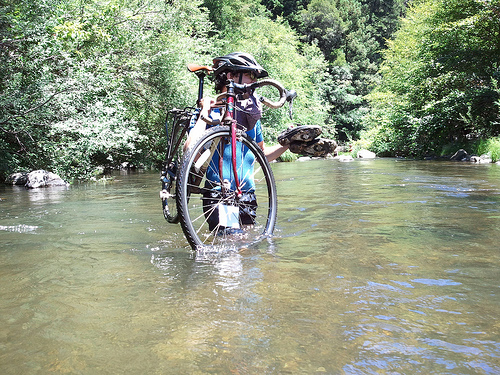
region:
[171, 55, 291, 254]
a person carrying a bike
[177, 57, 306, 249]
a person wading through water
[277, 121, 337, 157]
a person carrying a pair of shoes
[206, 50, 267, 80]
a black bike helmet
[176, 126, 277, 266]
the front wheel of a bike in the water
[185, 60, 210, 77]
an orange bike seat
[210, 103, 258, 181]
a person wearing a blue shirt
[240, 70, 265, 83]
a person wearing glasses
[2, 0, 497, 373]
a stream surrounded by trees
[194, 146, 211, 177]
a reflector in bike spokes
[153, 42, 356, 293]
the bike is in the water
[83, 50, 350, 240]
the man is in the water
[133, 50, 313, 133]
the man is wearing a helmet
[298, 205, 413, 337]
the water is calm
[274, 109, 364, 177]
the man is holding his shoes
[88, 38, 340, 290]
the man is walking in water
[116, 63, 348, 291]
the water is past the mans knees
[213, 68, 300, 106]
the man has on sunglasses.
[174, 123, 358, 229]
the bike has red on it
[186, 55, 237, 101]
the seat is red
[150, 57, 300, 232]
man is carrying bike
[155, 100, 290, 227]
black wheel on bike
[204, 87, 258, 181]
red frame on bike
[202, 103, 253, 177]
man has blue shirt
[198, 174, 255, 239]
man has black pants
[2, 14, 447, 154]
green trees behind man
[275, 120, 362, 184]
man is carrying shoes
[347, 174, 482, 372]
water is dark grey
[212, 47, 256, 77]
man has grey helmet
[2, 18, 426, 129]
thick forest of trees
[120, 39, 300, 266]
man carrying bike across the river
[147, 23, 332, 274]
man carrying bike through water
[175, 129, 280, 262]
black wheel of bike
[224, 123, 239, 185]
red frame of bike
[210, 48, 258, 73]
silver and black bike helmet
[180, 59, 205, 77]
brown bike seat on bike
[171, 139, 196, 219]
thick mountain bike wheels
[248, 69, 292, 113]
curved white handle bars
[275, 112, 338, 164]
shoes of biker in hands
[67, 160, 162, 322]
large stream of water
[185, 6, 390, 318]
person walking in river with bike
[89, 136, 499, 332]
river flowing through forest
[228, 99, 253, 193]
red metal of bicycle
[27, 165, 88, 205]
rocks on side of river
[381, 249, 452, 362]
light shining off water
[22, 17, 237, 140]
thick green trees by river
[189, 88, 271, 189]
blue shirt on mountain biker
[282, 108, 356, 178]
shoes in hand of biker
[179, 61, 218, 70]
orange seat of bike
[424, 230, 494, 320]
large stones under water